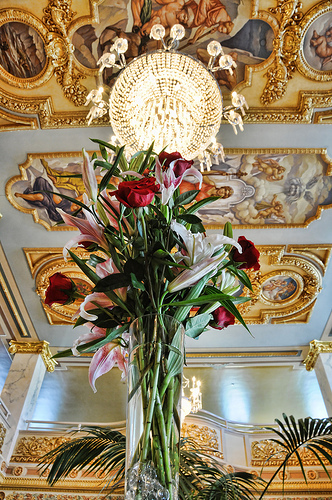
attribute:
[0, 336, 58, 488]
pillar — marble, stone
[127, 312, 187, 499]
vase — glass, clear, tall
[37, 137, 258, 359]
bouquet — floral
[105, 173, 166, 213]
rose — red, long stemmed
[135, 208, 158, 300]
stem — green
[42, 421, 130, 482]
palm frond — leafy, green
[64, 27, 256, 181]
chandelier — lit, hanging, encircled, crystal, large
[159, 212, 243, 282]
flower — white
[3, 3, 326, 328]
panels — painted, ornate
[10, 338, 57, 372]
molding — gold, decorative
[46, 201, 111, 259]
flower — pink, white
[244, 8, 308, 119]
decorations — gold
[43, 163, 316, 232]
mural — painted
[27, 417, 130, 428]
railing — ornamental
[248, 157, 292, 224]
cherubs — painted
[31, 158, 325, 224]
panel — painted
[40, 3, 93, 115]
cornucopias — overflowing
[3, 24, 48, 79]
painting — oval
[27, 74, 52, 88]
frame — gold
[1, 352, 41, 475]
column — marble